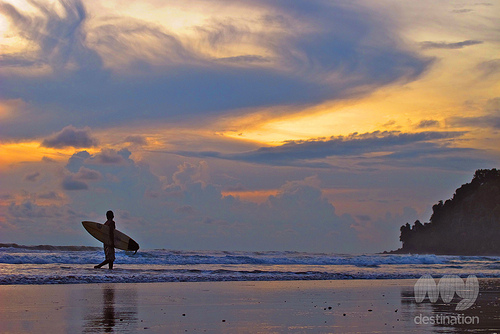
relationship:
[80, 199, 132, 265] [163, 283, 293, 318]
man on beach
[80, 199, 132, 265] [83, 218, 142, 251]
man carrying surboard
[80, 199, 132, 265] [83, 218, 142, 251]
man with surboard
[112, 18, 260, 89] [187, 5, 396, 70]
clouds in sky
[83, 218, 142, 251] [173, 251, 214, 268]
surboard in ocean